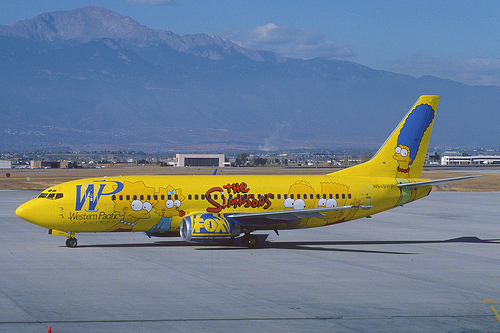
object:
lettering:
[73, 179, 125, 210]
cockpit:
[39, 190, 68, 213]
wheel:
[66, 237, 77, 246]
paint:
[395, 105, 435, 160]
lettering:
[204, 182, 273, 213]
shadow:
[56, 236, 500, 255]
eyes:
[165, 199, 174, 208]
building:
[174, 154, 231, 167]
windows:
[56, 192, 64, 199]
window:
[111, 195, 117, 201]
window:
[125, 195, 130, 201]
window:
[146, 194, 151, 200]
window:
[160, 194, 165, 200]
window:
[188, 194, 193, 200]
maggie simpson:
[149, 185, 186, 233]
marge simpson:
[391, 104, 435, 206]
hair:
[395, 103, 435, 165]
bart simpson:
[318, 181, 362, 225]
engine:
[178, 213, 242, 244]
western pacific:
[67, 209, 123, 220]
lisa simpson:
[104, 181, 159, 232]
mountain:
[0, 3, 499, 149]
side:
[10, 92, 475, 243]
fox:
[193, 215, 227, 233]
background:
[0, 0, 500, 170]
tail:
[362, 94, 439, 175]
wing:
[228, 205, 360, 224]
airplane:
[14, 92, 476, 247]